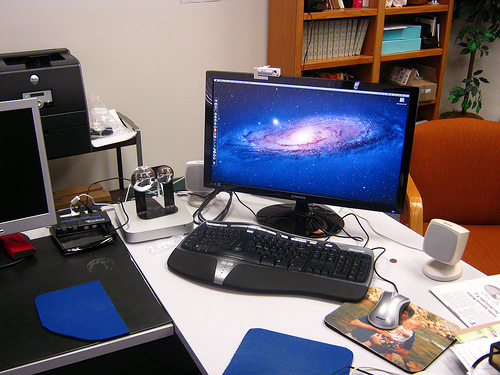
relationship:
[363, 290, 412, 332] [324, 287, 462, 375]
mouse on mouse pad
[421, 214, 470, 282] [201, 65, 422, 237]
speaker for a computer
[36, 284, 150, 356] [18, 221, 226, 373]
pad on desk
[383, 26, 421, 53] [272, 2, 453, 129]
two boxes in bookcase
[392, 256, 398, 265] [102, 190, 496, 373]
penny sitting on desktop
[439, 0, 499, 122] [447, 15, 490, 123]
houseplant sitting in corner